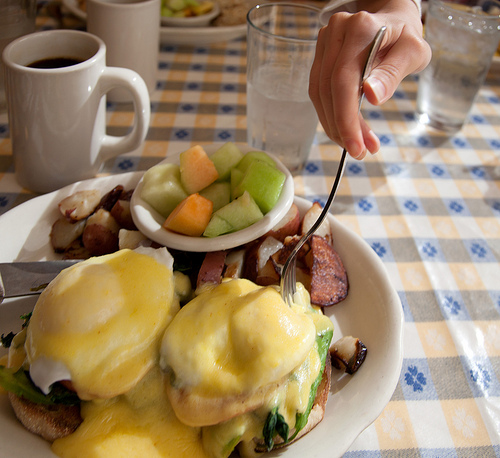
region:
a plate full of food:
[14, 171, 405, 456]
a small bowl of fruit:
[141, 151, 292, 238]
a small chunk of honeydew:
[232, 133, 269, 200]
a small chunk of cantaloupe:
[182, 145, 213, 185]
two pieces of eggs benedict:
[48, 289, 292, 429]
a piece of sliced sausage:
[301, 251, 372, 301]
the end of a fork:
[261, 261, 315, 306]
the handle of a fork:
[298, 168, 362, 232]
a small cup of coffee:
[30, 35, 142, 160]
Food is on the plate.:
[75, 255, 253, 457]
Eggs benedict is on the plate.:
[0, 247, 172, 442]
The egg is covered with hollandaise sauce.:
[75, 250, 156, 392]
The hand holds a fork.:
[281, 4, 433, 303]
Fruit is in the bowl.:
[163, 159, 267, 216]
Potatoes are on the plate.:
[312, 236, 347, 305]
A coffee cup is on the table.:
[5, 28, 152, 164]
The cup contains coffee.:
[25, 54, 84, 69]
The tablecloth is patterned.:
[410, 179, 499, 327]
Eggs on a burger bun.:
[6, 247, 326, 455]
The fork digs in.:
[281, 138, 343, 307]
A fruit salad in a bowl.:
[128, 143, 290, 240]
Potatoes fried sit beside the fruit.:
[48, 188, 140, 256]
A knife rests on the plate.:
[3, 252, 118, 294]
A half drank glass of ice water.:
[238, 2, 328, 172]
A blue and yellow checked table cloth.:
[383, 191, 475, 441]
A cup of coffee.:
[4, 26, 155, 194]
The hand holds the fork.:
[280, 10, 398, 295]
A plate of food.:
[4, 145, 423, 450]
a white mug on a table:
[0, 25, 149, 190]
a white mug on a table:
[86, 0, 158, 101]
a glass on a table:
[248, 3, 336, 180]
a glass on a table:
[409, 2, 498, 131]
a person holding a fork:
[277, 21, 387, 308]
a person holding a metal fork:
[278, 16, 388, 306]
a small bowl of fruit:
[128, 135, 295, 255]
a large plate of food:
[0, 169, 406, 456]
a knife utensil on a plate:
[1, 257, 148, 304]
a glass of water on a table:
[414, 4, 499, 134]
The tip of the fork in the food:
[269, 279, 306, 301]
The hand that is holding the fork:
[324, 5, 408, 160]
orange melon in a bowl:
[175, 151, 217, 194]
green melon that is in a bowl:
[215, 196, 268, 221]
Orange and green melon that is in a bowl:
[154, 154, 294, 251]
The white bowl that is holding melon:
[119, 139, 296, 253]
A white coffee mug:
[13, 36, 145, 198]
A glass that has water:
[247, 5, 324, 180]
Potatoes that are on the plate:
[64, 194, 344, 306]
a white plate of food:
[0, 153, 411, 456]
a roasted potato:
[310, 235, 347, 306]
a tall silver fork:
[282, 20, 389, 297]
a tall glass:
[242, 0, 327, 179]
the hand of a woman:
[303, 0, 435, 170]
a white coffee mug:
[0, 25, 155, 187]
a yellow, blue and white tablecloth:
[289, 79, 499, 456]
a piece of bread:
[8, 389, 75, 443]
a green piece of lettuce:
[263, 402, 296, 451]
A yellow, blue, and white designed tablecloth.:
[4, 12, 496, 456]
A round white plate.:
[0, 166, 406, 456]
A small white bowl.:
[126, 137, 303, 246]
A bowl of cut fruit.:
[124, 132, 300, 241]